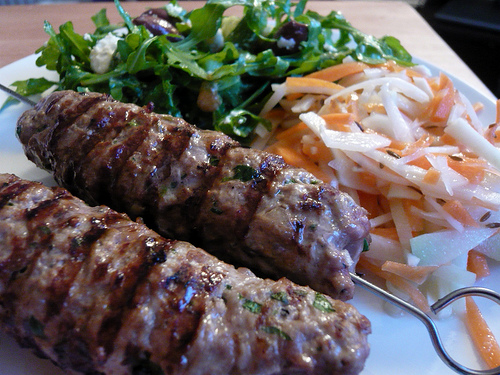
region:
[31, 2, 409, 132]
a green tossed salad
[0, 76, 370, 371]
grilled meat on a skewer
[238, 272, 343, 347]
seasoning in the grilled meat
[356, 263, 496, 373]
a metal skewer with a round top handle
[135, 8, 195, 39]
a marinated greek black olive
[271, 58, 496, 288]
shredded carrots and cabbage with fennel seed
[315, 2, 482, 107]
a light wood table top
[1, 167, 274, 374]
steak on a plate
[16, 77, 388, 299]
steak on a plate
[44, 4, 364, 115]
salad on white plate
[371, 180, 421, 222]
carrot strips on plate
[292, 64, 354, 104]
carrot strips on plate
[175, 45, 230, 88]
lettuce strips on plate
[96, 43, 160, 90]
lettuce strips on plate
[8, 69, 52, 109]
lettuce strips on plate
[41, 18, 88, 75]
lettuce strips on plate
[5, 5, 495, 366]
Meal on a plate.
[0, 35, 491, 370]
Plate is white.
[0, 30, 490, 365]
Plate is round.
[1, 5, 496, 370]
Plate on a wooden table.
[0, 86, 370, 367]
Grilled lamb on a skewer.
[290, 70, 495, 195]
Sliced daikon carrot salad.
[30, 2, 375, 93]
Greens next to the lamb skewer and sliced carrots.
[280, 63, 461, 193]
Carrots are cut in thin slices.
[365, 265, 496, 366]
The skewer is made of metal.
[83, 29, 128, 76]
Feta cheese on the greens.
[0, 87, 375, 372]
these are two pieces of meat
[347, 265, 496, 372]
this is a metal skewer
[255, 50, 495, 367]
these are some vegetables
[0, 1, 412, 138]
this is a salad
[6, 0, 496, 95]
this is a wood table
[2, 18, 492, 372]
this is a white plate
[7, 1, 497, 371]
this is a plate of food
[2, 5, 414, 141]
these are green and leafy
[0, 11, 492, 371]
the plate was on the table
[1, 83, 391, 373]
two pieces of meat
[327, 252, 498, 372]
skewer sticking out of the top of the meat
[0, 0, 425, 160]
pile of green leaves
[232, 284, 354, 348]
green specks on the meat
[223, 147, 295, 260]
char mark on the meat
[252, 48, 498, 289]
pile of shredded cheese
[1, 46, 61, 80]
edge of the plate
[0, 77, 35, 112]
skewer sticking out of the bottom of the meat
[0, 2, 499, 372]
food on a white plate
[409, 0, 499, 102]
edge of the table